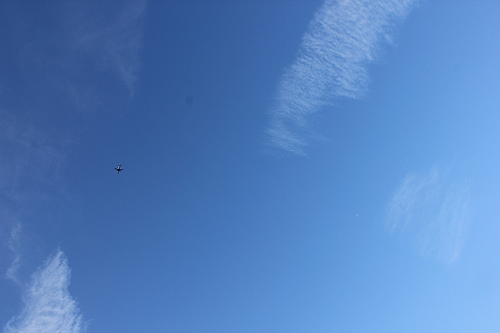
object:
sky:
[0, 0, 499, 331]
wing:
[119, 168, 125, 172]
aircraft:
[113, 163, 124, 175]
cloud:
[380, 157, 499, 264]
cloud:
[0, 219, 90, 332]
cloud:
[0, 124, 90, 211]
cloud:
[0, 0, 148, 115]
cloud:
[259, 0, 422, 160]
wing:
[114, 167, 119, 172]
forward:
[0, 1, 499, 163]